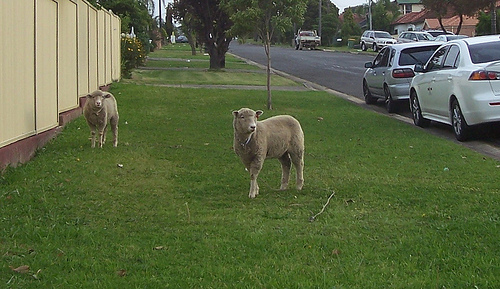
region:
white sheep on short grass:
[225, 101, 309, 206]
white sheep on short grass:
[82, 91, 149, 152]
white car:
[422, 23, 494, 138]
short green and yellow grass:
[338, 193, 369, 231]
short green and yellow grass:
[380, 191, 441, 241]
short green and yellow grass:
[307, 238, 352, 276]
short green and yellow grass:
[185, 188, 236, 250]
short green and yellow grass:
[64, 216, 112, 248]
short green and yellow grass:
[125, 176, 173, 220]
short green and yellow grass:
[101, 181, 165, 223]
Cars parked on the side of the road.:
[360, 38, 498, 143]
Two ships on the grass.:
[75, 86, 317, 198]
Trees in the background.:
[90, 0, 498, 115]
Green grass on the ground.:
[0, 42, 495, 285]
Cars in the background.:
[356, 23, 473, 53]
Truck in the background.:
[290, 24, 322, 51]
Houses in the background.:
[332, 3, 499, 51]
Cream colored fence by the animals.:
[1, 1, 133, 148]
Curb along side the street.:
[220, 46, 497, 155]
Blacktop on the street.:
[209, 33, 499, 145]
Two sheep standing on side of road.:
[80, 84, 312, 199]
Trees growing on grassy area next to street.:
[176, 1, 308, 109]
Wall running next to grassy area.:
[1, 0, 125, 166]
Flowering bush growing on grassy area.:
[121, 32, 154, 79]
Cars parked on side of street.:
[360, 33, 499, 143]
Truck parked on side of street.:
[289, 28, 329, 52]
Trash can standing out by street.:
[341, 34, 357, 52]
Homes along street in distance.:
[391, 1, 498, 39]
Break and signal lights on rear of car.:
[464, 64, 498, 85]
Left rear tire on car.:
[441, 94, 481, 141]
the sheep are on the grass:
[70, 73, 455, 273]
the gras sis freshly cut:
[74, 155, 291, 280]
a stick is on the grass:
[293, 160, 380, 282]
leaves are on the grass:
[20, 166, 119, 246]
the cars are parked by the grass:
[346, 26, 491, 143]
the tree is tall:
[242, 29, 357, 179]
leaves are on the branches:
[235, 13, 337, 40]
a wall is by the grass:
[18, 59, 213, 156]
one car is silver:
[360, 43, 437, 99]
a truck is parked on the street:
[275, 21, 377, 63]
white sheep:
[217, 97, 325, 199]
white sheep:
[76, 85, 136, 143]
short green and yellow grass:
[324, 212, 346, 227]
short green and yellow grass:
[162, 178, 191, 219]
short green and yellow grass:
[189, 228, 222, 255]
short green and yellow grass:
[84, 208, 118, 233]